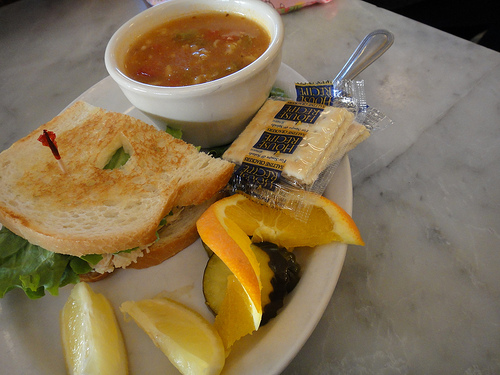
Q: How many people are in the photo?
A: Zero.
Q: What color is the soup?
A: Red.